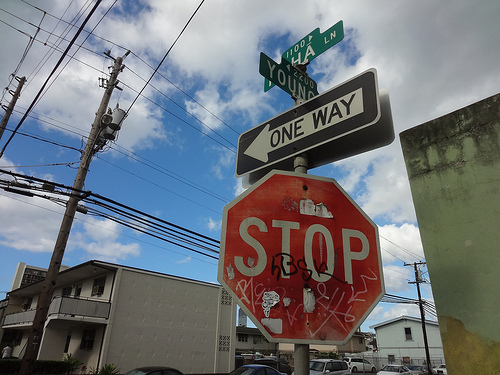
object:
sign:
[235, 67, 382, 177]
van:
[290, 358, 353, 374]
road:
[347, 369, 381, 375]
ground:
[353, 367, 382, 374]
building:
[0, 257, 237, 374]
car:
[374, 363, 412, 375]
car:
[341, 356, 376, 374]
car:
[432, 362, 448, 372]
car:
[231, 363, 288, 373]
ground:
[426, 128, 468, 173]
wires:
[0, 165, 220, 260]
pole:
[18, 57, 124, 374]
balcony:
[43, 294, 110, 327]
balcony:
[1, 308, 39, 327]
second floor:
[0, 260, 235, 327]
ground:
[381, 173, 397, 233]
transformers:
[95, 102, 128, 151]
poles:
[20, 56, 123, 374]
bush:
[85, 360, 120, 374]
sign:
[264, 19, 344, 91]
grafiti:
[230, 251, 378, 340]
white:
[378, 326, 401, 346]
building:
[235, 306, 279, 374]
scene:
[0, 0, 499, 374]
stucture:
[398, 93, 499, 373]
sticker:
[260, 290, 281, 317]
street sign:
[258, 51, 320, 103]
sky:
[0, 0, 499, 334]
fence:
[362, 353, 441, 369]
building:
[368, 314, 446, 372]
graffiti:
[230, 250, 380, 338]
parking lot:
[233, 350, 447, 375]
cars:
[241, 357, 293, 374]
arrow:
[243, 86, 364, 163]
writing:
[266, 118, 305, 149]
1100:
[284, 39, 305, 59]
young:
[266, 59, 316, 102]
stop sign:
[217, 167, 386, 345]